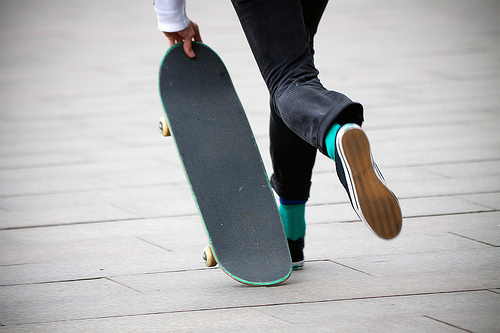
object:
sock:
[275, 203, 306, 241]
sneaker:
[287, 238, 307, 269]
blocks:
[389, 0, 499, 331]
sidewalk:
[0, 0, 500, 333]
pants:
[231, 0, 366, 218]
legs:
[239, 1, 365, 244]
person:
[146, 0, 403, 270]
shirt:
[151, 0, 189, 33]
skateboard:
[156, 38, 295, 289]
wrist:
[150, 0, 191, 33]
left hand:
[161, 21, 204, 57]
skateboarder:
[150, 0, 405, 270]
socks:
[276, 199, 307, 247]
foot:
[331, 123, 405, 240]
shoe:
[281, 238, 306, 271]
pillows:
[154, 0, 190, 32]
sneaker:
[334, 122, 403, 241]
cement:
[36, 258, 187, 332]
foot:
[269, 188, 308, 270]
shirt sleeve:
[151, 0, 193, 33]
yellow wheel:
[158, 116, 173, 136]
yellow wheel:
[202, 246, 217, 266]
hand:
[163, 18, 205, 57]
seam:
[180, 3, 188, 27]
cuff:
[154, 0, 190, 33]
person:
[152, 0, 403, 270]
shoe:
[333, 124, 403, 241]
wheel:
[158, 117, 171, 137]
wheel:
[203, 246, 218, 267]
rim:
[157, 48, 231, 286]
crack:
[0, 249, 214, 287]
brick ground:
[0, 0, 500, 333]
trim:
[157, 41, 295, 286]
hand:
[158, 18, 206, 58]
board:
[155, 40, 294, 285]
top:
[155, 41, 236, 95]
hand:
[161, 22, 205, 57]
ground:
[0, 0, 500, 333]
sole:
[342, 129, 402, 240]